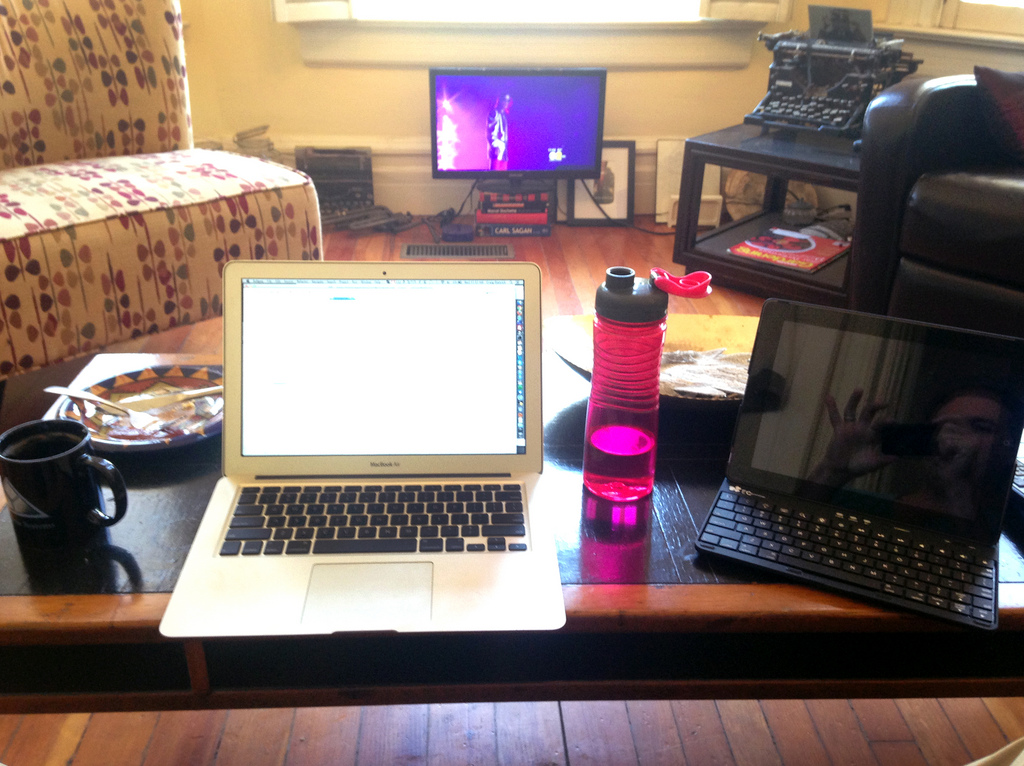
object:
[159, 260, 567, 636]
laptop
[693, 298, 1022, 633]
laptop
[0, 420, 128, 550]
mug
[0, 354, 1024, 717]
desk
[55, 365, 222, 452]
plate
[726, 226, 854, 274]
book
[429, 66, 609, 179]
tv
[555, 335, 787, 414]
bowl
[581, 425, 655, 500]
water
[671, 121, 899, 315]
table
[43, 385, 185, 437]
fork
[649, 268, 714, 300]
cap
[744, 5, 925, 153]
typewriter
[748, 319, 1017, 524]
screen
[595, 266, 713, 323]
top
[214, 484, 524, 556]
keys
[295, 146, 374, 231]
radio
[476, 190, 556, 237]
books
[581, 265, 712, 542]
water bottle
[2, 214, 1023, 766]
floor